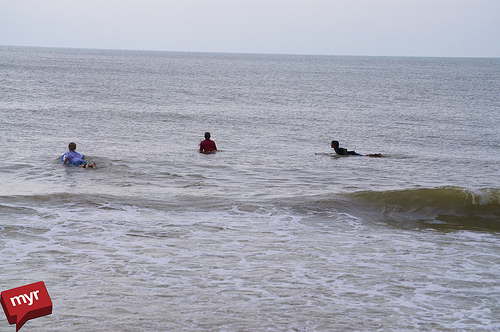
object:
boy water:
[61, 142, 97, 170]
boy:
[61, 142, 97, 170]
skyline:
[0, 35, 500, 67]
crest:
[296, 182, 499, 204]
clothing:
[199, 139, 216, 152]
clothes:
[65, 151, 83, 164]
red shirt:
[200, 139, 217, 153]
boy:
[331, 140, 383, 157]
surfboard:
[314, 151, 391, 157]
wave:
[282, 183, 498, 208]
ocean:
[0, 49, 498, 332]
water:
[2, 50, 499, 332]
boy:
[199, 132, 218, 154]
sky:
[0, 0, 500, 57]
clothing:
[334, 148, 358, 156]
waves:
[0, 103, 268, 127]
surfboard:
[62, 155, 97, 169]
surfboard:
[197, 144, 228, 152]